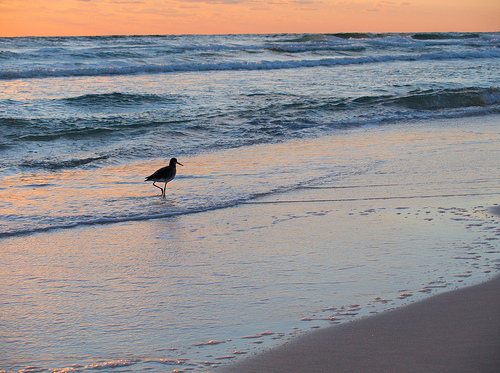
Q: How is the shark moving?
A: No shark.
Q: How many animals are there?
A: One.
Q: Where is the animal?
A: In the water.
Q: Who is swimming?
A: No one.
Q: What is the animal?
A: A bird.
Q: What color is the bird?
A: Black.